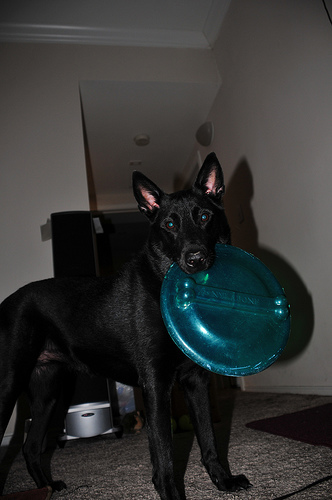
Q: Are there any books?
A: No, there are no books.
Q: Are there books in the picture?
A: No, there are no books.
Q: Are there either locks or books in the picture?
A: No, there are no books or locks.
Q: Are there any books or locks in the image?
A: No, there are no books or locks.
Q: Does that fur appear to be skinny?
A: Yes, the fur is skinny.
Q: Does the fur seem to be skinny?
A: Yes, the fur is skinny.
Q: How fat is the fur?
A: The fur is skinny.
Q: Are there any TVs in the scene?
A: No, there are no tvs.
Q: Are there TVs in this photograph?
A: No, there are no tvs.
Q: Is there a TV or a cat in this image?
A: No, there are no televisions or cats.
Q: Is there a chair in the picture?
A: No, there are no chairs.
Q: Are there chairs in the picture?
A: No, there are no chairs.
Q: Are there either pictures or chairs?
A: No, there are no chairs or pictures.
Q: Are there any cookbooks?
A: No, there are no cookbooks.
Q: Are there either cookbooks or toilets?
A: No, there are no cookbooks or toilets.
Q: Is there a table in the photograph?
A: No, there are no tables.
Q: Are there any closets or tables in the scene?
A: No, there are no tables or closets.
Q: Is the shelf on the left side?
A: Yes, the shelf is on the left of the image.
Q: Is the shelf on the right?
A: No, the shelf is on the left of the image.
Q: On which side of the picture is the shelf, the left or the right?
A: The shelf is on the left of the image.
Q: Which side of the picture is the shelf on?
A: The shelf is on the left of the image.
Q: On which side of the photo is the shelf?
A: The shelf is on the left of the image.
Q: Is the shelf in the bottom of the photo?
A: Yes, the shelf is in the bottom of the image.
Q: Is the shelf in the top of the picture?
A: No, the shelf is in the bottom of the image.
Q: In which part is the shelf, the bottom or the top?
A: The shelf is in the bottom of the image.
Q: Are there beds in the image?
A: No, there are no beds.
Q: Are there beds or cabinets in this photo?
A: No, there are no beds or cabinets.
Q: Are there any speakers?
A: Yes, there is a speaker.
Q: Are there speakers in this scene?
A: Yes, there is a speaker.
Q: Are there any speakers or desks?
A: Yes, there is a speaker.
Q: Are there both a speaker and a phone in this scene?
A: No, there is a speaker but no phones.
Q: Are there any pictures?
A: No, there are no pictures.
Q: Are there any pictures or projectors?
A: No, there are no pictures or projectors.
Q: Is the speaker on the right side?
A: No, the speaker is on the left of the image.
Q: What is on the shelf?
A: The speaker is on the shelf.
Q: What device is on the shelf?
A: The device is a speaker.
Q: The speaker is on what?
A: The speaker is on the shelf.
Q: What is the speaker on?
A: The speaker is on the shelf.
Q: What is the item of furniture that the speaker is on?
A: The piece of furniture is a shelf.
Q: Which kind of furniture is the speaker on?
A: The speaker is on the shelf.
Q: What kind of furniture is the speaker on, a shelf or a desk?
A: The speaker is on a shelf.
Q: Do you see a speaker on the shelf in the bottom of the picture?
A: Yes, there is a speaker on the shelf.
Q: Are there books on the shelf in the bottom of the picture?
A: No, there is a speaker on the shelf.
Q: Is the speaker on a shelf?
A: Yes, the speaker is on a shelf.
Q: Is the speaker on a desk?
A: No, the speaker is on a shelf.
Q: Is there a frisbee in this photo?
A: Yes, there is a frisbee.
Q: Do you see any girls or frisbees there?
A: Yes, there is a frisbee.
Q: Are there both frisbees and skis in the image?
A: No, there is a frisbee but no skis.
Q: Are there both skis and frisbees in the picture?
A: No, there is a frisbee but no skis.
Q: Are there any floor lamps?
A: No, there are no floor lamps.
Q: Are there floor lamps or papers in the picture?
A: No, there are no floor lamps or papers.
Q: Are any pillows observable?
A: No, there are no pillows.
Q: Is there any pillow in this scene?
A: No, there are no pillows.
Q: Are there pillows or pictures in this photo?
A: No, there are no pillows or pictures.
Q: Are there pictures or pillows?
A: No, there are no pillows or pictures.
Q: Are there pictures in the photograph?
A: No, there are no pictures.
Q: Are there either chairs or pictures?
A: No, there are no pictures or chairs.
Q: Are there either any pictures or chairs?
A: No, there are no pictures or chairs.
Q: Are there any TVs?
A: No, there are no tvs.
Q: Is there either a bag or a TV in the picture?
A: No, there are no televisions or bags.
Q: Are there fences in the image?
A: No, there are no fences.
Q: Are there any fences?
A: No, there are no fences.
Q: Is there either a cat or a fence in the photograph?
A: No, there are no fences or cats.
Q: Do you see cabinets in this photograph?
A: No, there are no cabinets.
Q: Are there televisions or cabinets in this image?
A: No, there are no cabinets or televisions.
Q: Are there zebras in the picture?
A: No, there are no zebras.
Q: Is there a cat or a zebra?
A: No, there are no zebras or cats.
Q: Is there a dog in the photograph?
A: Yes, there is a dog.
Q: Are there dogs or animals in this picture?
A: Yes, there is a dog.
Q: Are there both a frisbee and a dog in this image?
A: Yes, there are both a dog and a frisbee.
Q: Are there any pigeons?
A: No, there are no pigeons.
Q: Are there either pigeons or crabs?
A: No, there are no pigeons or crabs.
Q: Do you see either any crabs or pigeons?
A: No, there are no pigeons or crabs.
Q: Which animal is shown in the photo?
A: The animal is a dog.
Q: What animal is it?
A: The animal is a dog.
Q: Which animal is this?
A: This is a dog.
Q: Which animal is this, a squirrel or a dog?
A: This is a dog.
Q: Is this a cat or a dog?
A: This is a dog.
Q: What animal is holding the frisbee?
A: The dog is holding the frisbee.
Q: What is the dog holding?
A: The dog is holding the frisbee.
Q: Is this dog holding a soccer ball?
A: No, the dog is holding the frisbee.